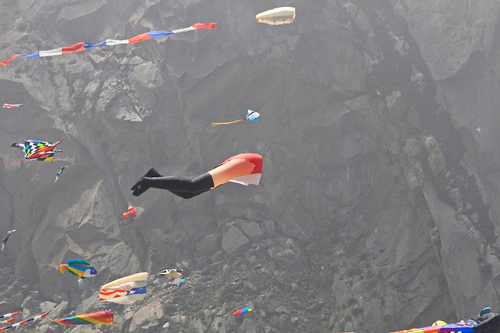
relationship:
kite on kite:
[8, 136, 66, 163] [8, 136, 66, 163]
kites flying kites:
[5, 10, 310, 74] [128, 145, 268, 197]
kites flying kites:
[5, 10, 310, 74] [197, 97, 269, 137]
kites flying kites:
[5, 10, 310, 74] [8, 132, 65, 169]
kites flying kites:
[5, 10, 310, 74] [219, 296, 258, 320]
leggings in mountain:
[130, 164, 212, 201] [0, 0, 499, 332]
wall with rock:
[328, 133, 453, 241] [305, 300, 323, 315]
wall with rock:
[328, 133, 453, 241] [126, 56, 168, 101]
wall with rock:
[328, 133, 453, 241] [425, 129, 445, 153]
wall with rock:
[328, 133, 453, 241] [228, 279, 242, 289]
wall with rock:
[328, 133, 453, 241] [53, 175, 124, 244]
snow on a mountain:
[35, 295, 67, 331] [3, 2, 490, 324]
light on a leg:
[143, 172, 209, 183] [124, 147, 296, 240]